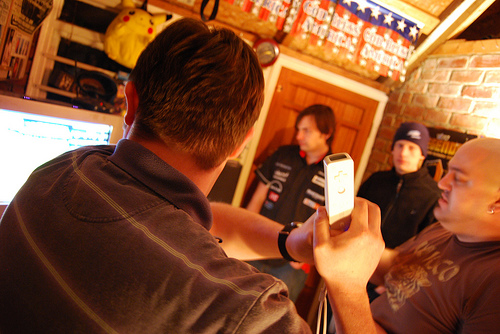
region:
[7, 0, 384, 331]
A man in the foreground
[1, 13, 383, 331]
A back view of a person's head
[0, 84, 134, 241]
A TV screen in the background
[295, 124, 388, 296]
Man is holding a controller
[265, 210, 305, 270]
Man is wearing a wristwatch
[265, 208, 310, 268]
Wristwatch is black in color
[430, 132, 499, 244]
Man in the background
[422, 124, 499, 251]
A side view of a man's head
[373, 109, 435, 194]
Man is wearing a knit cap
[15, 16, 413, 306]
the man is playing a video game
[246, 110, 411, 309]
man is holding a remote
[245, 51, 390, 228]
the door is closed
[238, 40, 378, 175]
the door is brown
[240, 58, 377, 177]
the door is made of wood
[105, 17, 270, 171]
the man`s hair is brown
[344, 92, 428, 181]
man is wearing a hat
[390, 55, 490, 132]
the wall is made of bricks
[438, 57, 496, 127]
a light on the bricks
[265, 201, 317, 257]
man is wearing a watch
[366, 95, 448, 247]
man wearing blue hat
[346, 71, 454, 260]
man wearing black jacket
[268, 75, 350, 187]
man has brown hair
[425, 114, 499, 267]
man does not have hair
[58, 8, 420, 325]
person holding remote control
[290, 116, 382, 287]
remote is white and square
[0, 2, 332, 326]
person wearing striped shirt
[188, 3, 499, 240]
banner hanging above door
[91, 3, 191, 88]
yellow smiling stuffed animal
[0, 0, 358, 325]
person watching tv screen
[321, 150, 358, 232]
white wii remote in a man's hand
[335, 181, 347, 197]
circular button on a wii remote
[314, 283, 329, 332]
white cord hanging from a wii remote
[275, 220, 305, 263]
black watch on a man's wrist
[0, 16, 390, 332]
man holding a wii remote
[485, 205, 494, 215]
silver hoop earring in a man's ear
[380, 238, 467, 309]
golden design on a dark colored shirt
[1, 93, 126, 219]
powered on television screen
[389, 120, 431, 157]
dark colored beanie on a man's head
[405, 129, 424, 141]
white design on dark colored beanie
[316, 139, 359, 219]
wii remote in person's hand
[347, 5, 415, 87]
red white and blue banner on the wall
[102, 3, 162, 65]
pikachu hanging on the wall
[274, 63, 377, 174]
wooden door behind the man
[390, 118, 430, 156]
beanie hat on the man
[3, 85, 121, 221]
tv screen behind the man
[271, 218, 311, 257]
watch on the man's wrist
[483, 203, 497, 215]
earring in the man's ear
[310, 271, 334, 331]
string hanging down from the wii remote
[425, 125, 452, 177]
poster on the wall